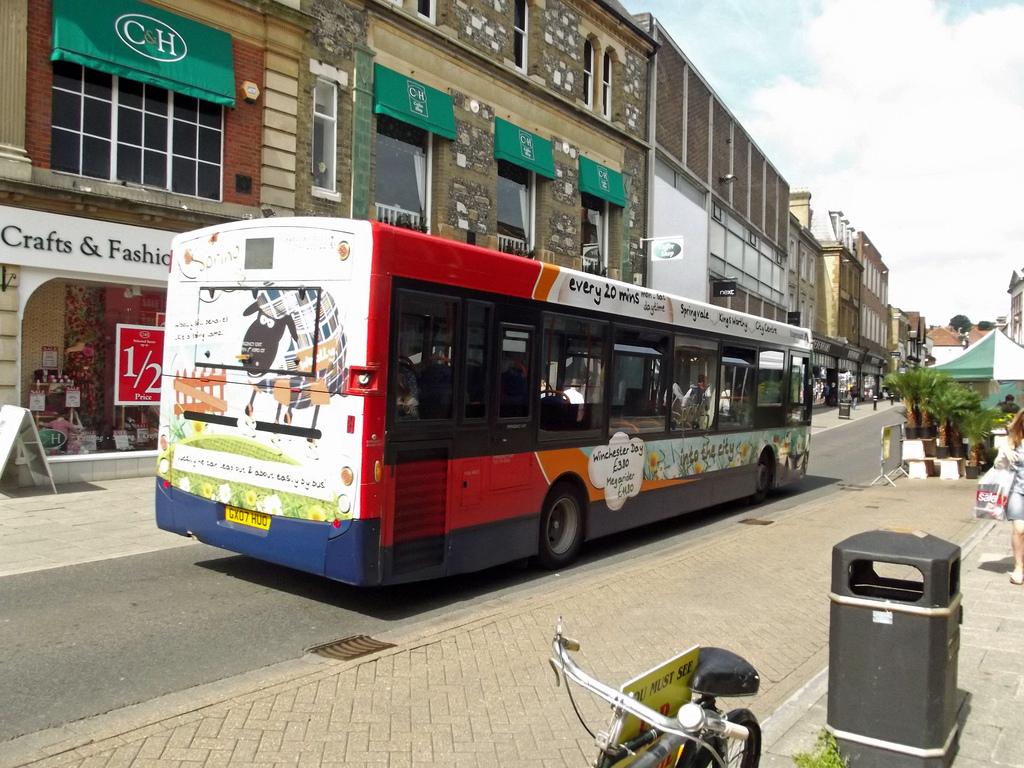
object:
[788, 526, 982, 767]
trash can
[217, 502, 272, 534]
license plate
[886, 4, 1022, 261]
clouds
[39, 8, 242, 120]
greencanopies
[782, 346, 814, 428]
windows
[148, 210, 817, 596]
bus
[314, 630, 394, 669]
grate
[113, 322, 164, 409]
poster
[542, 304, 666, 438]
stripe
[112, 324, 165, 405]
redsign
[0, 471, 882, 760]
curb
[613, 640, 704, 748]
sign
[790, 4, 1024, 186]
sky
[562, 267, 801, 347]
lettering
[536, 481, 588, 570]
tire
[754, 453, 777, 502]
tire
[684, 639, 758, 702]
seat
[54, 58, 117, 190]
window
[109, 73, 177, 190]
window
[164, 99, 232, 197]
window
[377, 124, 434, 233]
window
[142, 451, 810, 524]
stripe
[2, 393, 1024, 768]
street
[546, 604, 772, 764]
bicycle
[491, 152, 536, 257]
window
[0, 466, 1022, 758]
sidewalk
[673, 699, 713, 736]
circle